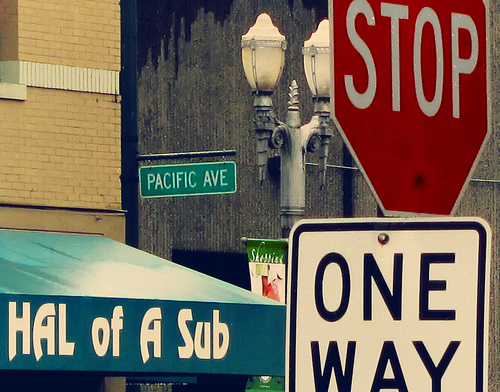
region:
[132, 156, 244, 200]
this is a posta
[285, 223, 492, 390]
this is a posta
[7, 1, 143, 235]
this is a bulding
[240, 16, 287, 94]
this is a bulb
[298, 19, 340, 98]
this is a bulb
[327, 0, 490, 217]
a STOP traffic sign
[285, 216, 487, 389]
a ONE WAY traffic sign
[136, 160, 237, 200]
a green street name sign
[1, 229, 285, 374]
a green business awning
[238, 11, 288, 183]
an overhead street light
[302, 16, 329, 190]
an overhead street light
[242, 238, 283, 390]
a street pole banner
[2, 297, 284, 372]
a business name sign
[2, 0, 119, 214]
a tan brick wall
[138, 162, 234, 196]
a PACIFIC AVE sign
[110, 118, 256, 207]
a sign on a pole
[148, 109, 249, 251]
a sign on a metal pole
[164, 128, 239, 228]
a pole with a sign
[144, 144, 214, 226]
a metal pole with sign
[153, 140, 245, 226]
a street sig on pole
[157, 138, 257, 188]
street sign on a metal pole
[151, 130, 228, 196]
pole with street sign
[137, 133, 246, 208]
metal pole with street sign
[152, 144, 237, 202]
green and white sign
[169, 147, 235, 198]
green street sign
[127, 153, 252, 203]
street sign on the pole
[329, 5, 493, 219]
stop sign above one way sign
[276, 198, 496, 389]
one way sign below stop sign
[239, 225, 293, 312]
banner on the pole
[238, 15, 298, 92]
light on the pole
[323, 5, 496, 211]
stop sign on the pole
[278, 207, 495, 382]
one way sign on the pole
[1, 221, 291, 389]
green awning on the wall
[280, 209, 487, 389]
black and white one way sign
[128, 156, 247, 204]
green and white street sign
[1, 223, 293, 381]
a green awning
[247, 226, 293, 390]
green and white banner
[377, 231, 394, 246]
bolt on a one way sign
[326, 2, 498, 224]
red and white stop sign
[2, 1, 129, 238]
tan brick building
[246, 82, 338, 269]
metal grey lamp post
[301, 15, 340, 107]
light globe on the right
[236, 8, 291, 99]
light globe on the left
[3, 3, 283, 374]
blue awning hanging from tan building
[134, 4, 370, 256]
green address sign hanging from black building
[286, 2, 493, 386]
red traffic sign over a white traffic sign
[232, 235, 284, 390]
green banner hanging from black building